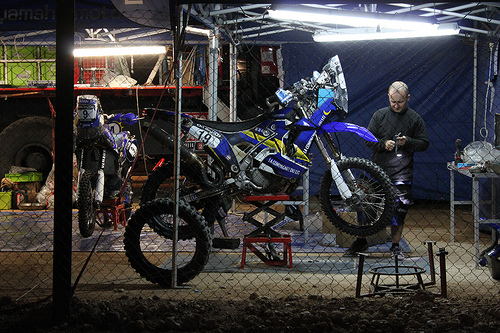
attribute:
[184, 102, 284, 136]
seat — black 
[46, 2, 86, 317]
pole — metal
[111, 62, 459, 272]
bike — black tire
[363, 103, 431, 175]
shirt — black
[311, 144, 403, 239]
tire — large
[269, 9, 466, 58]
lights — tube 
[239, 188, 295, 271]
motorcycle stand — red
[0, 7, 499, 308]
chainlink fence — chain link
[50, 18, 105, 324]
post — fence , shadows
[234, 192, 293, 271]
jack — red, black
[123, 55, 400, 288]
motorcycle — blue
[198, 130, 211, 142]
19 — number 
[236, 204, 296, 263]
lift — white , black 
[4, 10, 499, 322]
fencing — metal 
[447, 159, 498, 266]
table — metal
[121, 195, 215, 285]
tire — extra dirt motorcycle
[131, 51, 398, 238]
motorcycle — blue, yellow, white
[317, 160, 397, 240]
tire — Bike 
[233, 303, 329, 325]
pebbles — rock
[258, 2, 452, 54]
lights — fluorescent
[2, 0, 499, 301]
carport — workshop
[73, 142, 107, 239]
tire — rubber 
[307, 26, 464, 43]
fluorescent light — two fluorescent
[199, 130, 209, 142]
number — black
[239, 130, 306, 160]
stripe — yellow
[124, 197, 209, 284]
tire — black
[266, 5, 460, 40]
lighting — fluorescent, overhead